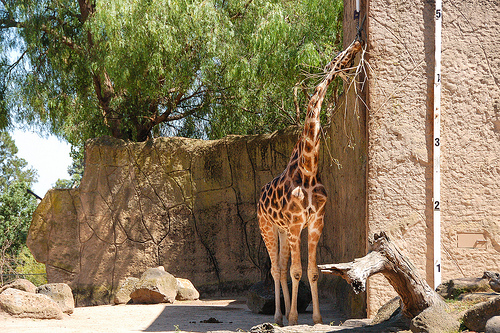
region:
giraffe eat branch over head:
[256, 34, 365, 331]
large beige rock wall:
[66, 140, 272, 294]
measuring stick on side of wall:
[430, 6, 447, 288]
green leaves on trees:
[116, 12, 196, 78]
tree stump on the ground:
[317, 233, 448, 320]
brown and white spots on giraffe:
[262, 178, 305, 220]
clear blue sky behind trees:
[19, 125, 84, 188]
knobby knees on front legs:
[280, 255, 325, 288]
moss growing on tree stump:
[440, 294, 456, 307]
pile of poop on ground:
[186, 312, 246, 327]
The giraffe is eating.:
[232, 28, 367, 331]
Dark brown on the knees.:
[287, 265, 322, 283]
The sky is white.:
[22, 130, 65, 186]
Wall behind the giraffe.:
[97, 155, 284, 282]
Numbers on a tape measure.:
[426, 7, 449, 282]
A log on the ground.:
[351, 255, 491, 320]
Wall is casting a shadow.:
[167, 297, 281, 327]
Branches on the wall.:
[321, 40, 372, 100]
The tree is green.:
[130, 9, 282, 76]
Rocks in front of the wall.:
[97, 255, 198, 307]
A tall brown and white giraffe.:
[252, 32, 369, 329]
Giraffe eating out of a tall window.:
[253, 35, 365, 327]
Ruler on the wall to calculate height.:
[423, 0, 456, 290]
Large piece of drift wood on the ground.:
[321, 231, 498, 329]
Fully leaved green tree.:
[4, 1, 353, 135]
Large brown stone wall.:
[48, 135, 253, 301]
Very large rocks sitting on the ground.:
[108, 262, 203, 310]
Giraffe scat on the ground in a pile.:
[182, 312, 247, 324]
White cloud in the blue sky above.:
[24, 135, 69, 185]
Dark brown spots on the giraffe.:
[264, 182, 292, 224]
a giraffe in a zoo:
[228, 23, 430, 330]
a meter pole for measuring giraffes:
[424, 2, 451, 322]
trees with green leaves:
[27, 5, 402, 130]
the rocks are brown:
[2, 131, 349, 315]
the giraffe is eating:
[242, 6, 471, 318]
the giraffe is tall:
[177, 22, 421, 329]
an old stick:
[302, 212, 469, 329]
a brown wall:
[330, 2, 497, 272]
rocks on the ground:
[2, 281, 208, 323]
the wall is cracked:
[20, 121, 355, 314]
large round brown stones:
[1, 271, 76, 324]